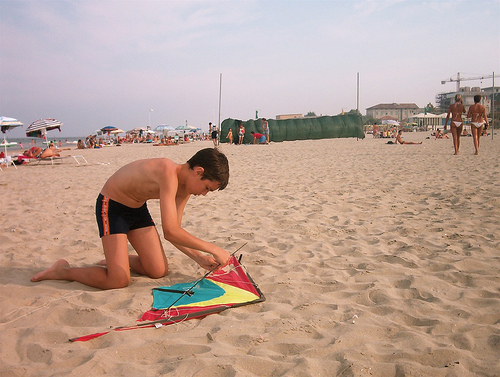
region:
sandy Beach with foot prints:
[260, 151, 480, 373]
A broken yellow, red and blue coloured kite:
[58, 241, 318, 347]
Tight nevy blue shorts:
[96, 191, 156, 236]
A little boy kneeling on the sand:
[25, 140, 316, 335]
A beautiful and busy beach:
[5, 48, 498, 373]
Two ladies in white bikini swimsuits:
[448, 94, 491, 156]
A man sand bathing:
[388, 129, 423, 159]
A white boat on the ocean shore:
[0, 141, 18, 149]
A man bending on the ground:
[252, 130, 270, 151]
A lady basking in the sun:
[16, 141, 94, 166]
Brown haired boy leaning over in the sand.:
[29, 145, 234, 287]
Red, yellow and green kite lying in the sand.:
[65, 250, 265, 342]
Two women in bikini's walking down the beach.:
[441, 94, 488, 155]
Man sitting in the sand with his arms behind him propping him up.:
[393, 129, 423, 147]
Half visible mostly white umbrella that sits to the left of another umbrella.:
[2, 115, 24, 161]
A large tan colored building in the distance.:
[365, 100, 419, 129]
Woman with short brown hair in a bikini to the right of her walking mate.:
[466, 90, 488, 155]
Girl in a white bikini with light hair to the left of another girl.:
[440, 92, 469, 154]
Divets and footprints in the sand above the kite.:
[265, 233, 357, 305]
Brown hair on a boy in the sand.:
[187, 142, 231, 189]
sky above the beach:
[107, 23, 198, 80]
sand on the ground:
[332, 203, 419, 277]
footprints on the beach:
[303, 248, 418, 346]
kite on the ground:
[159, 251, 255, 328]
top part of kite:
[237, 281, 277, 323]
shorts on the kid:
[68, 191, 161, 263]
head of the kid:
[191, 136, 248, 198]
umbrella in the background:
[26, 106, 68, 153]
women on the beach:
[434, 91, 499, 138]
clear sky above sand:
[75, 24, 159, 65]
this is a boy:
[63, 137, 253, 273]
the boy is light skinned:
[132, 179, 148, 187]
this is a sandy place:
[335, 236, 441, 363]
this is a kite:
[168, 272, 253, 332]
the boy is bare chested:
[118, 161, 177, 195]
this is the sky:
[81, 48, 173, 109]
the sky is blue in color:
[249, 25, 288, 67]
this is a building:
[378, 102, 403, 119]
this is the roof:
[378, 100, 403, 107]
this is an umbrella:
[21, 118, 51, 134]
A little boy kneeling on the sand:
[15, 136, 290, 351]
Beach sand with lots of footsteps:
[271, 148, 460, 336]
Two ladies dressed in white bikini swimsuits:
[438, 89, 490, 156]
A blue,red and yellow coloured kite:
[69, 230, 299, 318]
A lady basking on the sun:
[19, 120, 71, 163]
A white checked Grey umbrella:
[26, 117, 65, 134]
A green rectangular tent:
[223, 108, 367, 140]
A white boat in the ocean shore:
[1, 137, 15, 148]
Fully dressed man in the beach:
[248, 131, 268, 148]